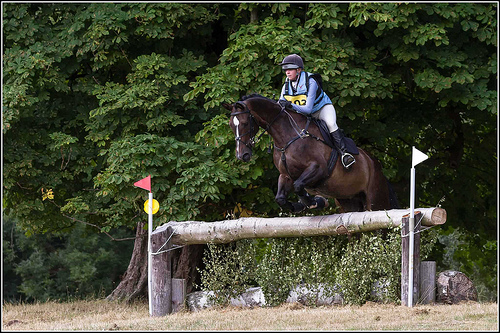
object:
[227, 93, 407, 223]
steed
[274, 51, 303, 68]
helmet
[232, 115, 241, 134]
mark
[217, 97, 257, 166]
face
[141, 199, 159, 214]
sign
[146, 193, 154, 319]
pole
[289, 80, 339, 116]
jacket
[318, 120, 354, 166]
boot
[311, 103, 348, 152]
pants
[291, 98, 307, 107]
number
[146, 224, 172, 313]
stump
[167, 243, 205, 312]
stump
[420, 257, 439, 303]
stump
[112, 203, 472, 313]
horse jump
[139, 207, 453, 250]
stump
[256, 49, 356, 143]
equestrian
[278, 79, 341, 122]
clothes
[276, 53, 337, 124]
girl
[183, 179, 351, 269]
hurdle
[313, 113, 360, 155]
saddle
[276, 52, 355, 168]
person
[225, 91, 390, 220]
horse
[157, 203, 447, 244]
trunk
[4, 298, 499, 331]
grass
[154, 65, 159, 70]
leaves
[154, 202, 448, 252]
log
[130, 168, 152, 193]
flag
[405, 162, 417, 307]
post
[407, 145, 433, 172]
flag